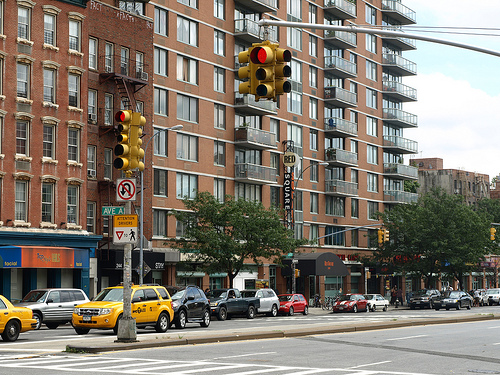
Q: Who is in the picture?
A: Noone.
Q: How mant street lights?
A: 8.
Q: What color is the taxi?
A: Yellow.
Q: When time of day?
A: Daytime.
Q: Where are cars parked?
A: Side of road.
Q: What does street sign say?
A: No u turn.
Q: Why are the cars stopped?
A: Light is red.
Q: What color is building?
A: Red.